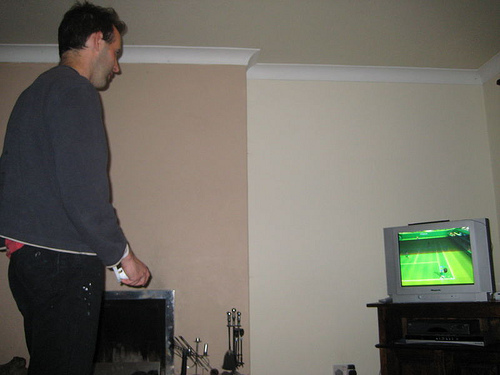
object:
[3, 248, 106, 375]
pants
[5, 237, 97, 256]
undershirt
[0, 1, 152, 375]
hand man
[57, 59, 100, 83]
neck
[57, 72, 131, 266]
arm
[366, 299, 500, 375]
entertainment center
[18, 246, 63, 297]
pockets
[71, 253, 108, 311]
pockets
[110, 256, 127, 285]
controller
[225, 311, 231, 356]
fireplace pokers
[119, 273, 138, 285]
fingers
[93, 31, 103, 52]
ear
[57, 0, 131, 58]
hair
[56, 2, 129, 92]
head